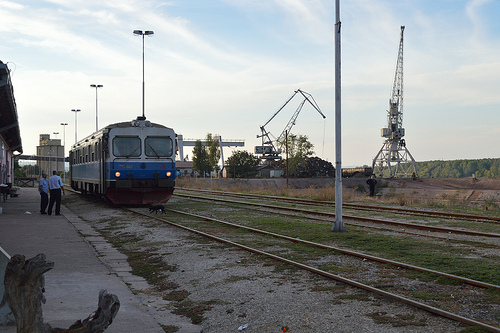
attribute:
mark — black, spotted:
[194, 242, 223, 264]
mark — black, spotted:
[197, 246, 223, 265]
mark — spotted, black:
[205, 246, 217, 264]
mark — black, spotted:
[195, 240, 217, 265]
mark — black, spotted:
[197, 251, 203, 259]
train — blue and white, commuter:
[66, 113, 178, 209]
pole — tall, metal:
[328, 3, 349, 234]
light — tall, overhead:
[133, 25, 153, 120]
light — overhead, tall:
[89, 81, 105, 129]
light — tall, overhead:
[54, 119, 72, 148]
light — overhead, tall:
[49, 127, 61, 141]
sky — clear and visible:
[151, 5, 338, 71]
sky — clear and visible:
[0, 2, 132, 81]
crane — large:
[368, 21, 418, 181]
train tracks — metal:
[171, 213, 450, 331]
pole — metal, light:
[326, 1, 353, 231]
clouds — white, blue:
[132, 58, 315, 100]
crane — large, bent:
[251, 85, 326, 175]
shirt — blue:
[46, 174, 61, 193]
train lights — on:
[112, 168, 172, 180]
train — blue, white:
[69, 116, 180, 205]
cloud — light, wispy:
[0, 1, 498, 97]